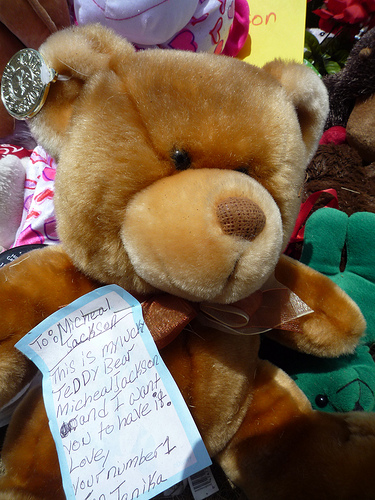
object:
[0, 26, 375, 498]
teddy bear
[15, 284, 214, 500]
note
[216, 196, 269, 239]
nose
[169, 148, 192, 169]
eye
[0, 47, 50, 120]
medallion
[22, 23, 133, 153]
ear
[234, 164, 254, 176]
eye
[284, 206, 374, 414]
green bear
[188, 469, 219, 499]
bar code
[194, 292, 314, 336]
ribbon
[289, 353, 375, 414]
face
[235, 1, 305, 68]
note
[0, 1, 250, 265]
teddy bear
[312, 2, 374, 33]
flower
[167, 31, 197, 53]
heart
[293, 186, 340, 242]
red ribbon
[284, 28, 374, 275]
teddy bear